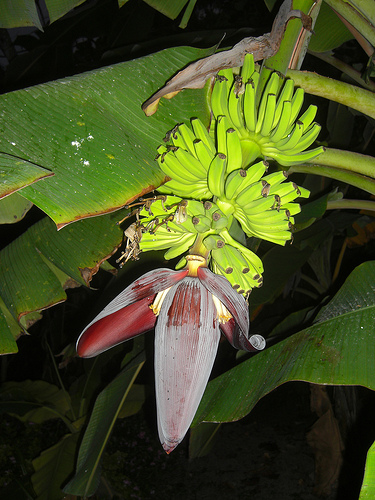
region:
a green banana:
[205, 151, 228, 200]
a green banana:
[199, 232, 226, 247]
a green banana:
[211, 244, 230, 274]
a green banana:
[222, 241, 248, 272]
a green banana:
[211, 211, 227, 230]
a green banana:
[193, 214, 212, 236]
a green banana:
[202, 198, 217, 217]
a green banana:
[164, 234, 194, 265]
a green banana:
[225, 127, 241, 174]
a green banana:
[274, 146, 325, 167]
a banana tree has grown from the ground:
[85, 42, 366, 389]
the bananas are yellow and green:
[120, 46, 352, 226]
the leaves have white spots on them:
[8, 75, 221, 248]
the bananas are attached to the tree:
[111, 42, 367, 360]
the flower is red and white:
[90, 265, 324, 460]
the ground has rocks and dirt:
[105, 411, 226, 489]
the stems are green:
[263, 16, 368, 166]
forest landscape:
[1, 2, 366, 381]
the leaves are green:
[3, 4, 365, 319]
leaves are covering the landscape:
[1, 30, 371, 343]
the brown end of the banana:
[216, 151, 227, 160]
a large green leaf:
[180, 259, 373, 466]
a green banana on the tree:
[260, 144, 328, 167]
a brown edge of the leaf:
[54, 173, 178, 233]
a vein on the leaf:
[81, 358, 146, 495]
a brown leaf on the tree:
[74, 265, 190, 362]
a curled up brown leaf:
[226, 330, 272, 355]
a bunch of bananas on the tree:
[205, 49, 329, 167]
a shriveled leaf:
[139, 6, 310, 121]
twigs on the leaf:
[116, 192, 166, 227]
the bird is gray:
[204, 5, 313, 69]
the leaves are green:
[2, 89, 133, 260]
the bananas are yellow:
[162, 118, 270, 272]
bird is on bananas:
[203, 10, 321, 123]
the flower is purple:
[104, 295, 252, 438]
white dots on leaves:
[324, 303, 358, 320]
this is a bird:
[184, 3, 310, 74]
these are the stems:
[314, 70, 370, 193]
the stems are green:
[298, 65, 373, 203]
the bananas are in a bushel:
[195, 75, 271, 289]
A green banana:
[205, 148, 226, 202]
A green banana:
[228, 166, 241, 199]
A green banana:
[225, 128, 243, 168]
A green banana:
[173, 144, 208, 180]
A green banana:
[212, 73, 231, 123]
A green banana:
[243, 77, 259, 132]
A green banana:
[241, 50, 256, 82]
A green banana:
[256, 223, 289, 231]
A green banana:
[230, 245, 246, 272]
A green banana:
[162, 243, 189, 255]